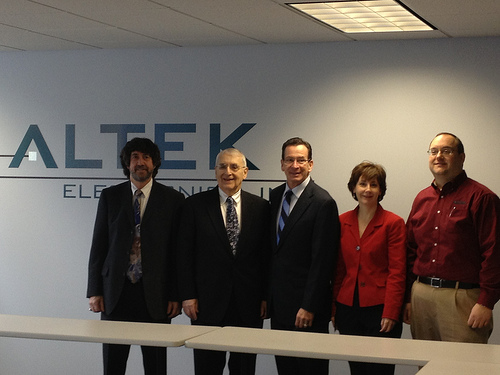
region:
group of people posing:
[80, 127, 492, 340]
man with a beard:
[99, 136, 175, 321]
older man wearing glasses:
[197, 141, 269, 347]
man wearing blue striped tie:
[272, 131, 334, 369]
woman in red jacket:
[341, 155, 408, 343]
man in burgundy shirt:
[422, 128, 499, 345]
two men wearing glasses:
[197, 138, 330, 340]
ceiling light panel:
[272, 4, 452, 46]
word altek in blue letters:
[7, 103, 274, 180]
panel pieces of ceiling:
[12, 9, 343, 61]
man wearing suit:
[84, 136, 179, 373]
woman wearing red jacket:
[336, 162, 406, 374]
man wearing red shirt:
[406, 132, 498, 374]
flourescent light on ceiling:
[285, 0, 436, 34]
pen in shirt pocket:
[446, 202, 460, 224]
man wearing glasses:
[425, 132, 467, 187]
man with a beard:
[116, 137, 163, 189]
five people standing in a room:
[84, 132, 498, 374]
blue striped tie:
[272, 185, 294, 247]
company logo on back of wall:
[1, 115, 259, 177]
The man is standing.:
[82, 134, 183, 373]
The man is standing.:
[171, 136, 269, 373]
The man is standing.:
[258, 130, 335, 373]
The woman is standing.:
[326, 150, 406, 374]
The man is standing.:
[396, 125, 498, 374]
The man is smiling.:
[400, 127, 499, 373]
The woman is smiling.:
[328, 156, 407, 373]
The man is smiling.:
[264, 130, 340, 373]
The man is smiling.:
[173, 138, 269, 374]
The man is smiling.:
[82, 134, 184, 374]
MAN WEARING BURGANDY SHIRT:
[455, 227, 465, 264]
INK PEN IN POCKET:
[449, 202, 457, 216]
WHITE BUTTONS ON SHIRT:
[433, 226, 436, 233]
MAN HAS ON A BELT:
[421, 280, 452, 285]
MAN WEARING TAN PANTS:
[452, 297, 467, 317]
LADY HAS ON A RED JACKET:
[363, 264, 385, 269]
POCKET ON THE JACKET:
[375, 277, 385, 287]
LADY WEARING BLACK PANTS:
[352, 318, 372, 330]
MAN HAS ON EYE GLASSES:
[286, 155, 311, 165]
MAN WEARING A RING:
[298, 318, 315, 328]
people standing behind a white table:
[50, 135, 499, 345]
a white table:
[8, 330, 483, 369]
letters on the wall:
[14, 119, 255, 171]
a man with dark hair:
[88, 148, 190, 314]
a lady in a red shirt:
[331, 167, 411, 356]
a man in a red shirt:
[408, 135, 497, 318]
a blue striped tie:
[275, 190, 291, 236]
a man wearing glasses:
[266, 125, 324, 184]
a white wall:
[11, 53, 496, 111]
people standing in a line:
[63, 120, 480, 342]